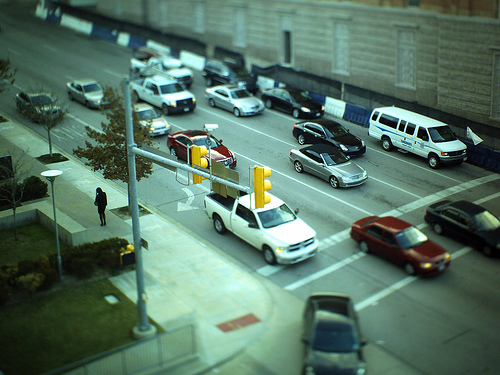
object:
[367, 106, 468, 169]
van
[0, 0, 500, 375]
road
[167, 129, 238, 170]
vehicle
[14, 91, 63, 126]
vehicle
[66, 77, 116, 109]
vehicle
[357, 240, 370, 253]
tire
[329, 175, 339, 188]
tire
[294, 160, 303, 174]
tire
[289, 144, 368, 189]
car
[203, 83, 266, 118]
car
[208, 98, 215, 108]
tire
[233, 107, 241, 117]
tire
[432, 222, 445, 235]
tire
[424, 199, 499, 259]
car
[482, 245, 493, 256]
tire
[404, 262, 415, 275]
tire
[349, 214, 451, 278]
car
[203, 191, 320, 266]
car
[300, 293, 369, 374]
car